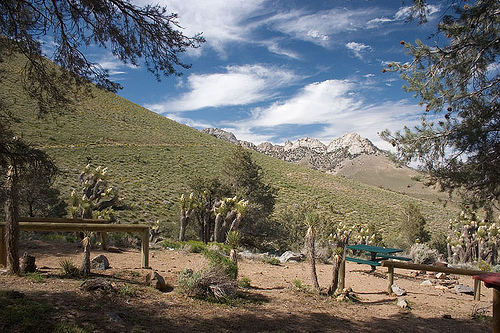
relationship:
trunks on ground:
[287, 223, 348, 300] [5, 235, 494, 330]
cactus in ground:
[64, 161, 129, 233] [5, 235, 494, 330]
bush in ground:
[171, 248, 259, 307] [5, 235, 494, 330]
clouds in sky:
[186, 57, 370, 125] [0, 0, 495, 182]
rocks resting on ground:
[421, 272, 475, 297] [5, 235, 494, 330]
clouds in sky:
[106, 6, 475, 167] [107, 27, 427, 129]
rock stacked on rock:
[384, 290, 425, 324] [377, 268, 409, 295]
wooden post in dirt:
[14, 220, 150, 275] [4, 226, 496, 331]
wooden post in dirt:
[383, 259, 486, 304] [4, 226, 496, 331]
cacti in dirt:
[297, 211, 359, 310] [2, 244, 498, 330]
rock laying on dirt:
[278, 249, 304, 264] [2, 244, 498, 330]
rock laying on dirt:
[390, 281, 407, 295] [2, 244, 498, 330]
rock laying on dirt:
[109, 266, 165, 288] [2, 244, 498, 330]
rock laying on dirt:
[89, 254, 109, 272] [2, 244, 498, 330]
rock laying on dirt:
[452, 284, 473, 294] [2, 244, 498, 330]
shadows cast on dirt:
[4, 264, 495, 330] [2, 244, 498, 330]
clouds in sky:
[186, 57, 370, 125] [0, 2, 498, 162]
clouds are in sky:
[186, 57, 370, 125] [244, 15, 379, 116]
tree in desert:
[194, 175, 232, 246] [2, 76, 498, 331]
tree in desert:
[224, 139, 278, 241] [2, 76, 498, 331]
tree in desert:
[398, 200, 427, 260] [2, 76, 498, 331]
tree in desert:
[1, 0, 208, 174] [2, 76, 498, 331]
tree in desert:
[379, 1, 497, 208] [2, 76, 498, 331]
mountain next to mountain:
[273, 138, 328, 172] [325, 131, 372, 163]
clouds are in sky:
[186, 57, 370, 125] [0, 2, 498, 162]